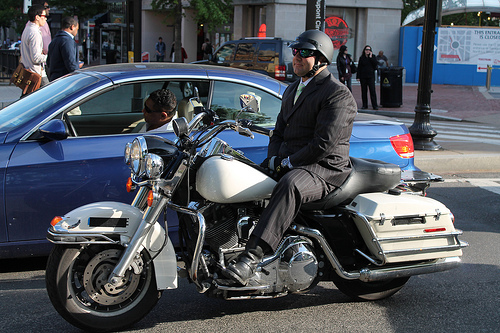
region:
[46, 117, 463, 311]
A motorcycle on the road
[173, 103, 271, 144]
The handlebars of the motorcycle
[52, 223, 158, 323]
The front tire of the motorcycle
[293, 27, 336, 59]
The man has a black helmet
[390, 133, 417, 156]
The rear light of the blue car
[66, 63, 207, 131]
The blue car has an open window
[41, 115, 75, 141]
The rear view mirror of the blue car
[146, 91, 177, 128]
A man is sitting in the blue car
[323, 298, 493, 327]
The street beneath the motorcycle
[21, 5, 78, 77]
People walking on the sidewalk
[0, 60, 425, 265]
A Blue two-doored car.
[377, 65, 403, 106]
A recycling bin.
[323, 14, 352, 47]
A round red neon sign in a window.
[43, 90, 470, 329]
A white motorcycle.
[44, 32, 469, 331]
A man riding a motorcycle.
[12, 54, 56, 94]
A brown satchel.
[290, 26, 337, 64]
A black motorcycle helmet.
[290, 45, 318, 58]
Black sunglasses.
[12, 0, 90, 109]
People walking down the road.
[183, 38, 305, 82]
A parked SUV.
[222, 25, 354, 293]
a man sitting on a motorcycle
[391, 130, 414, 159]
red taillight of a blue car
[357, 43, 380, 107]
a woman wearing all black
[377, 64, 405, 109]
a black garbage can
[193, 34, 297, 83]
a black van on a street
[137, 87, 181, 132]
man driving a blue car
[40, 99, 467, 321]
a silver motorcycle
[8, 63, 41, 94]
man carrying a brown leather bag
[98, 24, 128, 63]
a public phone booth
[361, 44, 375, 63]
a woman talking on a cellphone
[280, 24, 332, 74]
Head of a person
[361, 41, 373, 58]
Head of a person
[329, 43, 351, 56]
Head of a person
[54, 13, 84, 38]
Head of a person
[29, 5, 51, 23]
Head of a person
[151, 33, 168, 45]
Head of a person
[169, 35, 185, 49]
Head of a person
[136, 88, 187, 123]
Head of a person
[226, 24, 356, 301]
This is a person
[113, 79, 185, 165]
This is a person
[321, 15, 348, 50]
round sign in the window that is black with red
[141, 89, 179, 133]
person sitting in the car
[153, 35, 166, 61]
person standing in blue shirt and black vest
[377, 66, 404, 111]
black recycle bin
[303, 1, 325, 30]
black pole with white letters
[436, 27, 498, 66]
white map on the blue wall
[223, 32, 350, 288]
man sitting on motorcycle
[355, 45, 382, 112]
woman in black talking on her cell phone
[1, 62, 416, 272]
blue sedan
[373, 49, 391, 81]
man sitting on a bench